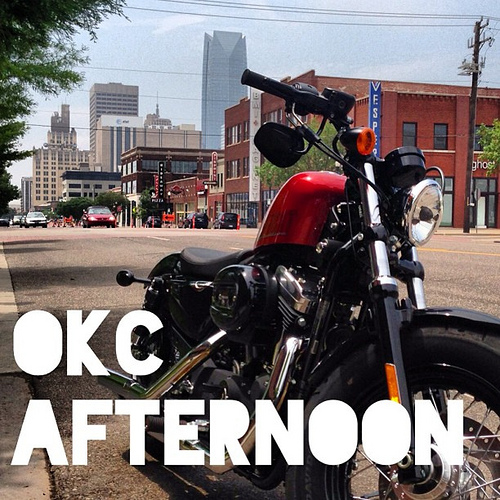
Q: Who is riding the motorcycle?
A: No one.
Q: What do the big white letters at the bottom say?
A: OKC AFTERNOON.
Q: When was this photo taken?
A: Daytime.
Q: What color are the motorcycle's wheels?
A: Black.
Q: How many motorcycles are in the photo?
A: One.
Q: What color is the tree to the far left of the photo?
A: Green.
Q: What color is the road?
A: Grey.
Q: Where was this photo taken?
A: On the side of a street.